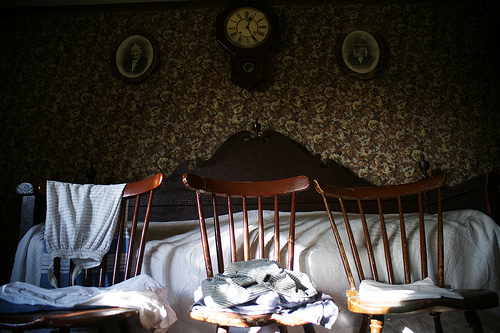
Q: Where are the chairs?
A: Foot of the bed.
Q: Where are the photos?
A: On the wall.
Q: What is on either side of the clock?
A: Photos.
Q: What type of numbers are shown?
A: Roman numerals.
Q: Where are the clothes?
A: On chairs.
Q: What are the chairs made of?
A: Wood.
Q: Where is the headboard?
A: Against wall.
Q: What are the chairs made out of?
A: Wood.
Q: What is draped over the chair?
A: Laundry.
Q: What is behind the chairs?
A: Bed.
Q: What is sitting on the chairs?
A: Laundry.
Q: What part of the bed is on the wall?
A: Head board.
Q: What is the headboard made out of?
A: Wood.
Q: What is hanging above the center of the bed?
A: Clock.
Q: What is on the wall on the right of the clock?
A: Portrait.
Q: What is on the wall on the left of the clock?
A: Portrait.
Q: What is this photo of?
A: A room.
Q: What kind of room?
A: A bedroom.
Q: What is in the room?
A: Chairs.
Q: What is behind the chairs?
A: A bed.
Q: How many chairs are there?
A: Three.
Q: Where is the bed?
A: Behind the chairs.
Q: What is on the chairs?
A: Clothing.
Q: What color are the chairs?
A: Brown.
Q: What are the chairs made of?
A: Wood.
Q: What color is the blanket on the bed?
A: White.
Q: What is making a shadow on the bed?
A: The slats of the chairs.